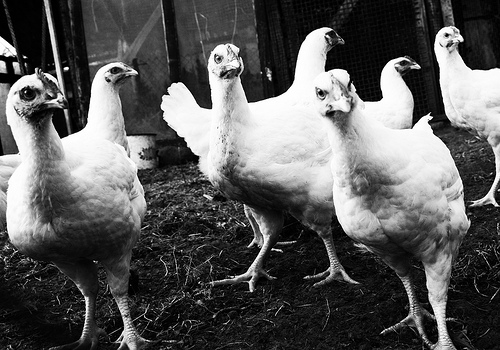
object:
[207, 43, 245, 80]
head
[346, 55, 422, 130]
chicken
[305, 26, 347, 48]
head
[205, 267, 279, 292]
feet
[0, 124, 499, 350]
ground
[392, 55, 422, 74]
head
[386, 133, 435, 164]
white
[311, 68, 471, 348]
chicken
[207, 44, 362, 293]
chicken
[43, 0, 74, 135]
metal pole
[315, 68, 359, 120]
head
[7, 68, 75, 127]
head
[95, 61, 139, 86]
head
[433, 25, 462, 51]
head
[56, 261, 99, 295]
leg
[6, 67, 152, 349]
chicken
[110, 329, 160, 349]
chicken feet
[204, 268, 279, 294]
chicken feet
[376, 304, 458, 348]
chicken feet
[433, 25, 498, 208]
chicken